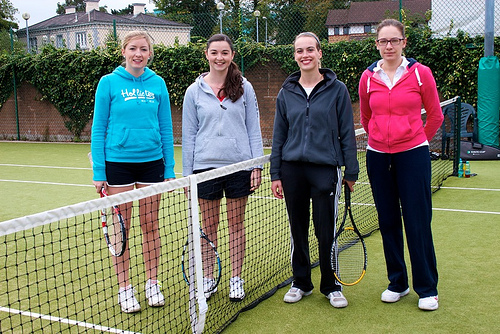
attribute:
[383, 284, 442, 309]
sneakers — white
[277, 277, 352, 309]
sneakers — white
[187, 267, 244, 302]
sneakers — white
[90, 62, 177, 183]
pull over — blue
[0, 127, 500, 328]
court — tennis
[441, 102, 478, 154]
chair — blue, plastic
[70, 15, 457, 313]
women — standing 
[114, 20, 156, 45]
hair — blonde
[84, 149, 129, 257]
racquet — red, white, blue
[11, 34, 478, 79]
plants — green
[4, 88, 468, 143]
wall — brick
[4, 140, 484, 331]
court — green, tennis, grass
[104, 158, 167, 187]
shorts — athletic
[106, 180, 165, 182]
trim — white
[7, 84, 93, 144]
wall — brick